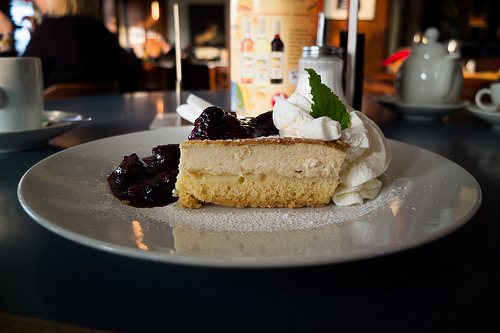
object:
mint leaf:
[305, 64, 352, 132]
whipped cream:
[277, 84, 391, 205]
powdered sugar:
[58, 153, 459, 229]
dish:
[17, 123, 484, 270]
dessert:
[110, 66, 393, 210]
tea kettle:
[390, 27, 467, 114]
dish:
[373, 95, 468, 122]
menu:
[219, 0, 323, 121]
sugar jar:
[298, 43, 348, 107]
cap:
[300, 44, 345, 59]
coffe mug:
[0, 55, 47, 133]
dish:
[0, 110, 86, 156]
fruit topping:
[111, 109, 284, 209]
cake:
[178, 124, 351, 213]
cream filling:
[182, 158, 341, 181]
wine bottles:
[271, 19, 285, 84]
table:
[3, 84, 499, 333]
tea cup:
[474, 81, 498, 113]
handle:
[474, 87, 496, 114]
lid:
[412, 29, 450, 58]